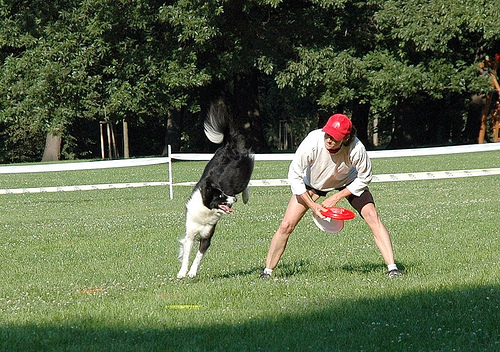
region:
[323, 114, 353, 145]
a red baseball cap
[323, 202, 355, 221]
a red frisbee made of plastic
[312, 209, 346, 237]
a white plastic frisbee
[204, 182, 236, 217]
a dog's excited face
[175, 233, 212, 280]
the front legs of the dog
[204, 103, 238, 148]
the long bushy tail of a dog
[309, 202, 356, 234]
two frisbees in a person's hands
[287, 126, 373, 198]
a white long sleeved shirt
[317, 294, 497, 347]
tiny white flowers in the shade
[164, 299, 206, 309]
a yellow patch on the ground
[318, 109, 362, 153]
person has read hat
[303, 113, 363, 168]
person is wearing a hat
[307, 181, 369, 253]
person holding red frisbee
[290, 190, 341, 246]
person holding white frisbee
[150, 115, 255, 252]
dog is in the air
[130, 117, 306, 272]
the dog is jumping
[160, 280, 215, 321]
a yellow frisbee in grass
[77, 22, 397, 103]
green trees in background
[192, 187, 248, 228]
dogs tongue sticking out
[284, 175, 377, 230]
person is wearing shorts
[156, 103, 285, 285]
the dog on the grass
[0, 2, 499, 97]
the trees with green leaves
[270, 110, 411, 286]
the man on the grass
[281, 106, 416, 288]
the man wearing hat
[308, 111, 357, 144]
the hat is red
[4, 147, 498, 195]
the fence behind the man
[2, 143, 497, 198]
the fence is white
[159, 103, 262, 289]
the dog is black and white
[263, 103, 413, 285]
the man holding the frisbees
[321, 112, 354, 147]
Red ball cap on a man.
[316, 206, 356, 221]
Red frisbee in a man's hands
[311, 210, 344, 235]
White frisbee in a man's hand.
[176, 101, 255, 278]
A white and black dog landing.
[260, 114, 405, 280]
A man with two frisbees and a red cap on.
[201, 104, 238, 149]
White and black tail on a dog.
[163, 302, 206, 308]
Yellow frisbee in the grass.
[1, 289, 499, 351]
Dark shadow on the grass.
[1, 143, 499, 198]
A white fence behind the person and dog.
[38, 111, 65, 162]
A thick grey tree trunk in the background.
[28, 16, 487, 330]
person playing frisbee with a dog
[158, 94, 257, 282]
black and white dog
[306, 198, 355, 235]
one red frisbee and one white frisbee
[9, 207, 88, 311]
small white flowers in the grass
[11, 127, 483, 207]
wooden white fence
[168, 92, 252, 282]
dog jumping in the air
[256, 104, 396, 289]
person holding two frisbees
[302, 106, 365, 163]
person wearing a red baseball hat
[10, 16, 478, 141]
tall green trees in the background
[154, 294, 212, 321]
yellow frisbee in the grass